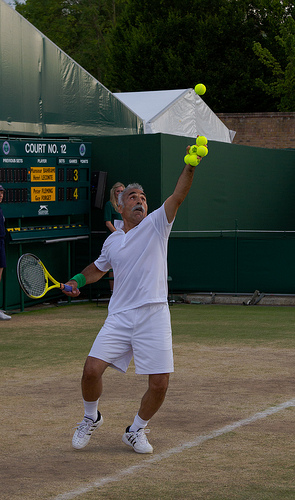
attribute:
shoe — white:
[69, 412, 102, 450]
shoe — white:
[121, 423, 152, 453]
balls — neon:
[182, 81, 208, 166]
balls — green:
[184, 82, 211, 166]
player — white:
[60, 134, 207, 448]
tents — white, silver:
[8, 18, 232, 154]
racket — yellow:
[9, 244, 84, 300]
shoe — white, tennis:
[124, 422, 153, 455]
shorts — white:
[79, 296, 206, 386]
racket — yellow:
[11, 239, 109, 338]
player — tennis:
[9, 123, 218, 458]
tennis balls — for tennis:
[163, 83, 221, 166]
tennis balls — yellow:
[184, 134, 209, 167]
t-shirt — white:
[86, 202, 181, 311]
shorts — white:
[82, 304, 175, 377]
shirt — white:
[94, 201, 176, 315]